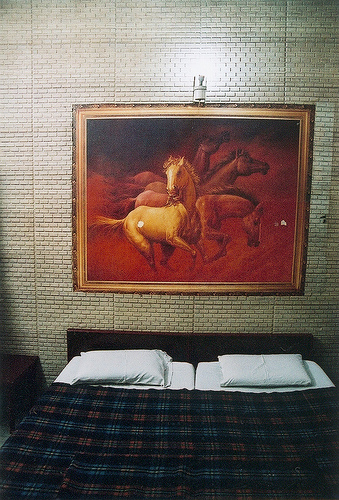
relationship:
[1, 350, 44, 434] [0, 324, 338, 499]
brown table next to bed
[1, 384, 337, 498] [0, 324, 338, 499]
plaid bedspread on bed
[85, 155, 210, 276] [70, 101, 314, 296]
horse in painting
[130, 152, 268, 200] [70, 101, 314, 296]
horse in painting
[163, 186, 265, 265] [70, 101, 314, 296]
horse in painting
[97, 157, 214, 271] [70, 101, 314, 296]
horse in painting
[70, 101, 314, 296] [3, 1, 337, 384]
painting on wall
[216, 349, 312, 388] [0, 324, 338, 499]
white pillow on bed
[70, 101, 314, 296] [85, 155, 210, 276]
painting has horse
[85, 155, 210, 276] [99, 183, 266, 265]
horse has horse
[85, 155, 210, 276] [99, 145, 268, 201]
horse has horse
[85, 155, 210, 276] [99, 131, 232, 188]
horse has horse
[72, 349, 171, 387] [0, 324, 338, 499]
white pillow on bed